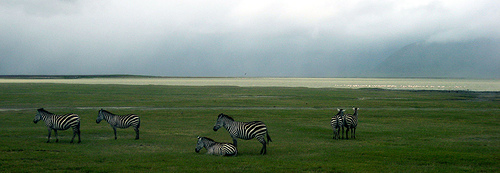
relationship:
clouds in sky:
[1, 2, 497, 60] [1, 1, 499, 81]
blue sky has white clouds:
[1, 1, 499, 81] [1, 2, 497, 60]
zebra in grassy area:
[31, 107, 84, 146] [1, 82, 498, 172]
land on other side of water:
[0, 75, 263, 81] [1, 76, 499, 91]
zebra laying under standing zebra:
[193, 134, 239, 158] [212, 111, 273, 155]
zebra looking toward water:
[342, 107, 360, 140] [1, 76, 499, 91]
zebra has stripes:
[31, 107, 84, 146] [60, 111, 81, 131]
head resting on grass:
[192, 133, 216, 155] [1, 82, 498, 172]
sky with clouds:
[1, 1, 499, 81] [1, 2, 497, 60]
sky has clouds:
[1, 1, 499, 81] [1, 2, 497, 60]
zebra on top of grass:
[31, 107, 84, 146] [1, 82, 498, 172]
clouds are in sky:
[1, 2, 497, 60] [1, 1, 499, 81]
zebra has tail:
[212, 111, 273, 155] [262, 124, 274, 146]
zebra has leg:
[31, 107, 84, 146] [46, 127, 83, 144]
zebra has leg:
[94, 106, 142, 143] [108, 125, 142, 141]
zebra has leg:
[212, 111, 273, 155] [226, 135, 268, 158]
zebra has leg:
[328, 105, 345, 142] [328, 127, 342, 140]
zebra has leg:
[341, 104, 362, 141] [341, 127, 360, 142]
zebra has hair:
[31, 107, 84, 146] [37, 108, 56, 117]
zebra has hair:
[94, 106, 142, 143] [99, 107, 115, 117]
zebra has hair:
[193, 134, 239, 158] [200, 135, 217, 146]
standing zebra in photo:
[212, 113, 273, 156] [1, 1, 498, 169]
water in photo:
[1, 76, 499, 91] [1, 1, 498, 169]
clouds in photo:
[1, 2, 497, 60] [1, 1, 498, 169]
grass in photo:
[1, 82, 498, 172] [1, 1, 498, 169]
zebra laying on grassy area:
[193, 134, 239, 158] [1, 82, 500, 173]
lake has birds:
[1, 76, 499, 91] [240, 69, 250, 76]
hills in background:
[362, 1, 499, 82] [1, 1, 498, 80]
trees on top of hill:
[375, 1, 499, 80] [362, 1, 499, 82]